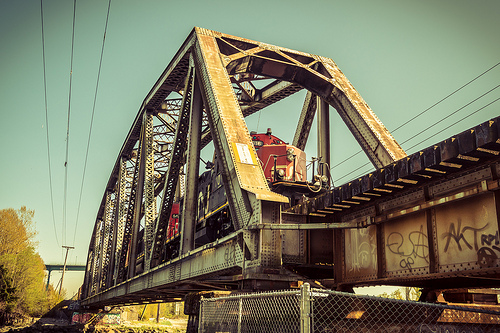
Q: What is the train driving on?
A: A bridge.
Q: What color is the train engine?
A: Red.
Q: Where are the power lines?
A: On both sides of the bridge.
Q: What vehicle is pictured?
A: A train.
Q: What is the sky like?
A: Clear.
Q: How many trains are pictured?
A: One.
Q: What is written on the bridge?
A: Graffiti.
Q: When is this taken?
A: Daytime.